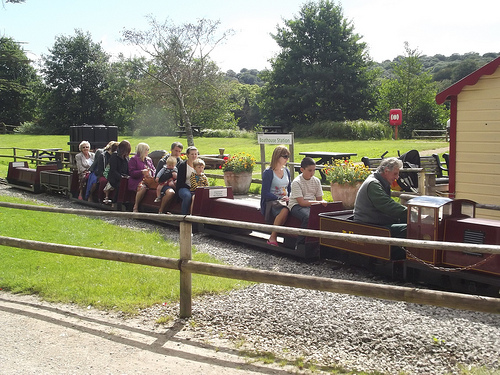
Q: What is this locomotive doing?
A: Riding rails.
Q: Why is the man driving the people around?
A: It's his job.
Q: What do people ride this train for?
A: Fun.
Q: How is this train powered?
A: By engine.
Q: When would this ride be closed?
A: Nighttime.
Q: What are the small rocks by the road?
A: Gravel.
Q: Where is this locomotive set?
A: A theme park.